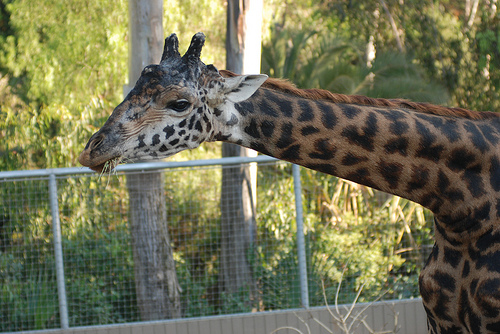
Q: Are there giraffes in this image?
A: Yes, there is a giraffe.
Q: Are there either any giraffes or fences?
A: Yes, there is a giraffe.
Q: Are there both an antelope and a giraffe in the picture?
A: No, there is a giraffe but no antelopes.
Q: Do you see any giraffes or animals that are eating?
A: Yes, the giraffe is eating.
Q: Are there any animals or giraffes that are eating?
A: Yes, the giraffe is eating.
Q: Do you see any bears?
A: No, there are no bears.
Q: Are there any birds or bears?
A: No, there are no bears or birds.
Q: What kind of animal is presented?
A: The animal is a giraffe.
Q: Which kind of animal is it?
A: The animal is a giraffe.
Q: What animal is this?
A: This is a giraffe.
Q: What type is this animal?
A: This is a giraffe.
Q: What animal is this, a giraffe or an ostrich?
A: This is a giraffe.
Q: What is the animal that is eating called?
A: The animal is a giraffe.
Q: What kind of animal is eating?
A: The animal is a giraffe.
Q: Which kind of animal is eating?
A: The animal is a giraffe.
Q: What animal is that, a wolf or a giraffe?
A: That is a giraffe.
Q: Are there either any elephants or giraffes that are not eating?
A: No, there is a giraffe but it is eating.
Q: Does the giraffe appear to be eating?
A: Yes, the giraffe is eating.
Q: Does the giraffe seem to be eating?
A: Yes, the giraffe is eating.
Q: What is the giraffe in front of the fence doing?
A: The giraffe is eating.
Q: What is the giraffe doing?
A: The giraffe is eating.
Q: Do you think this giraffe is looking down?
A: No, the giraffe is eating.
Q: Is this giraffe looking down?
A: No, the giraffe is eating.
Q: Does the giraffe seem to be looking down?
A: No, the giraffe is eating.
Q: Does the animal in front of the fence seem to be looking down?
A: No, the giraffe is eating.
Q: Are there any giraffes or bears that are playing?
A: No, there is a giraffe but it is eating.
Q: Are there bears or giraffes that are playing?
A: No, there is a giraffe but it is eating.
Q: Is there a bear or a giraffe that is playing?
A: No, there is a giraffe but it is eating.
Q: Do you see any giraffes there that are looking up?
A: No, there is a giraffe but it is eating.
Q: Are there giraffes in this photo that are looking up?
A: No, there is a giraffe but it is eating.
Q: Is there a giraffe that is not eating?
A: No, there is a giraffe but it is eating.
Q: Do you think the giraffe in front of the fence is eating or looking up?
A: The giraffe is eating.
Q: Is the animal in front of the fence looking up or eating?
A: The giraffe is eating.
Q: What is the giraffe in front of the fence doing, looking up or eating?
A: The giraffe is eating.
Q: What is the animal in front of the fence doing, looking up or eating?
A: The giraffe is eating.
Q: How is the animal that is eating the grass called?
A: The animal is a giraffe.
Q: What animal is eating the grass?
A: The animal is a giraffe.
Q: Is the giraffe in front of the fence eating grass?
A: Yes, the giraffe is eating grass.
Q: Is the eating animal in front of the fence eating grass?
A: Yes, the giraffe is eating grass.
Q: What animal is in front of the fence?
A: The giraffe is in front of the fence.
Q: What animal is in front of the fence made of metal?
A: The animal is a giraffe.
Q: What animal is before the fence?
A: The animal is a giraffe.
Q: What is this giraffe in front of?
A: The giraffe is in front of the fence.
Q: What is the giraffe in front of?
A: The giraffe is in front of the fence.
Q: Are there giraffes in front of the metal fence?
A: Yes, there is a giraffe in front of the fence.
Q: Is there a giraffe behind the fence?
A: No, the giraffe is in front of the fence.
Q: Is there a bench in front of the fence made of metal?
A: No, there is a giraffe in front of the fence.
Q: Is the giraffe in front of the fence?
A: Yes, the giraffe is in front of the fence.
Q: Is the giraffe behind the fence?
A: No, the giraffe is in front of the fence.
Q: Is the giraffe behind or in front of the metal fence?
A: The giraffe is in front of the fence.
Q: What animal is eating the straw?
A: The animal is a giraffe.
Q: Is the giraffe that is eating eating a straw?
A: Yes, the giraffe is eating a straw.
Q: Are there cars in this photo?
A: No, there are no cars.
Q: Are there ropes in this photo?
A: No, there are no ropes.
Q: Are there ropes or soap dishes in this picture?
A: No, there are no ropes or soap dishes.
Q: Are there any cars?
A: No, there are no cars.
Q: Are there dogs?
A: No, there are no dogs.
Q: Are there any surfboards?
A: No, there are no surfboards.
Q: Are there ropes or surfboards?
A: No, there are no surfboards or ropes.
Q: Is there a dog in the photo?
A: No, there are no dogs.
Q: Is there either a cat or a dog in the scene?
A: No, there are no dogs or cats.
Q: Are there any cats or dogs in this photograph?
A: No, there are no dogs or cats.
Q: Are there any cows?
A: No, there are no cows.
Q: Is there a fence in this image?
A: Yes, there is a fence.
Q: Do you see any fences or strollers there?
A: Yes, there is a fence.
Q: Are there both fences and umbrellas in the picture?
A: No, there is a fence but no umbrellas.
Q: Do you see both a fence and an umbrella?
A: No, there is a fence but no umbrellas.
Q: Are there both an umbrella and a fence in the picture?
A: No, there is a fence but no umbrellas.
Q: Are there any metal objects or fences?
A: Yes, there is a metal fence.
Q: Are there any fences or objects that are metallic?
A: Yes, the fence is metallic.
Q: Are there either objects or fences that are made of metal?
A: Yes, the fence is made of metal.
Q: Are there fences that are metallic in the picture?
A: Yes, there is a metal fence.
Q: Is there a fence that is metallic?
A: Yes, there is a fence that is metallic.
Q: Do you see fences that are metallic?
A: Yes, there is a fence that is metallic.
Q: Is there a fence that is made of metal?
A: Yes, there is a fence that is made of metal.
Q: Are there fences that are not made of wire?
A: Yes, there is a fence that is made of metal.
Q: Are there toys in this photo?
A: No, there are no toys.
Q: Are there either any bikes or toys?
A: No, there are no toys or bikes.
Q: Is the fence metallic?
A: Yes, the fence is metallic.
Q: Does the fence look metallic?
A: Yes, the fence is metallic.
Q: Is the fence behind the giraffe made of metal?
A: Yes, the fence is made of metal.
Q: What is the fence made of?
A: The fence is made of metal.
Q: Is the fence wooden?
A: No, the fence is metallic.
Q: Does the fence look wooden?
A: No, the fence is metallic.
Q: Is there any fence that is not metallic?
A: No, there is a fence but it is metallic.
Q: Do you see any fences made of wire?
A: No, there is a fence but it is made of metal.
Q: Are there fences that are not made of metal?
A: No, there is a fence but it is made of metal.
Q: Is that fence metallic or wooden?
A: The fence is metallic.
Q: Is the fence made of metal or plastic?
A: The fence is made of metal.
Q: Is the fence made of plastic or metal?
A: The fence is made of metal.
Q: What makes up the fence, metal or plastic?
A: The fence is made of metal.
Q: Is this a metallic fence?
A: Yes, this is a metallic fence.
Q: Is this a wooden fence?
A: No, this is a metallic fence.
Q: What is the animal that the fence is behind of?
A: The animal is a giraffe.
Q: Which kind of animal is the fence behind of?
A: The fence is behind the giraffe.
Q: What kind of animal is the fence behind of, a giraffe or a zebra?
A: The fence is behind a giraffe.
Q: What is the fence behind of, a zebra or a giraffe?
A: The fence is behind a giraffe.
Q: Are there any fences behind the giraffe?
A: Yes, there is a fence behind the giraffe.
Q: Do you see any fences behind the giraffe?
A: Yes, there is a fence behind the giraffe.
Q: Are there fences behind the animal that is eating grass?
A: Yes, there is a fence behind the giraffe.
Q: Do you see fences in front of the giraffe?
A: No, the fence is behind the giraffe.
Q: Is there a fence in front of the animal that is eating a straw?
A: No, the fence is behind the giraffe.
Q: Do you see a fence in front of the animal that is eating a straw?
A: No, the fence is behind the giraffe.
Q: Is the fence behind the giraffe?
A: Yes, the fence is behind the giraffe.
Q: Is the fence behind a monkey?
A: No, the fence is behind the giraffe.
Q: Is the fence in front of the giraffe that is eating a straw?
A: No, the fence is behind the giraffe.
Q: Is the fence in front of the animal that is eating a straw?
A: No, the fence is behind the giraffe.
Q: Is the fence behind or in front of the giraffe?
A: The fence is behind the giraffe.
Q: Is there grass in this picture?
A: Yes, there is grass.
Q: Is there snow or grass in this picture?
A: Yes, there is grass.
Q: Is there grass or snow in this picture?
A: Yes, there is grass.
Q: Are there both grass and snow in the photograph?
A: No, there is grass but no snow.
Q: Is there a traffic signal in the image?
A: No, there are no traffic lights.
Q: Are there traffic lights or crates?
A: No, there are no traffic lights or crates.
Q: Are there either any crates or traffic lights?
A: No, there are no traffic lights or crates.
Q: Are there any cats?
A: No, there are no cats.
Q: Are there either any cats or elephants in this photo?
A: No, there are no cats or elephants.